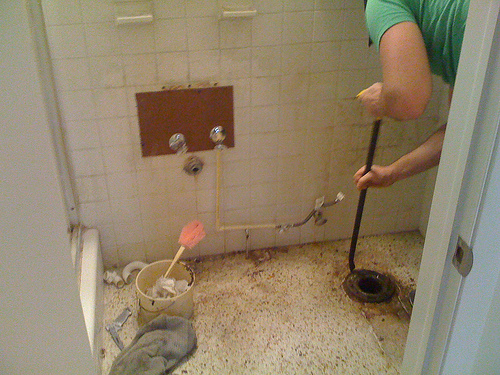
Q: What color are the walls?
A: White.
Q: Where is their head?
A: Not in the frame.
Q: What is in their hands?
A: A bar.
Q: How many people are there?
A: One.